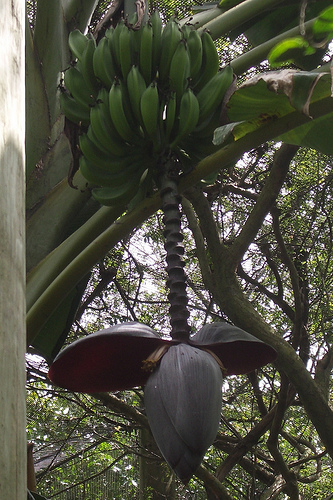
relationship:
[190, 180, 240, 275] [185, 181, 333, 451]
shadow on wood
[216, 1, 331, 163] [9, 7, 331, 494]
leaves on tree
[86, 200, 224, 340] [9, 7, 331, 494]
sky through tree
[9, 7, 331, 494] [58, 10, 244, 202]
tree under bananas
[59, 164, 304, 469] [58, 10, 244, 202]
part hanging bananas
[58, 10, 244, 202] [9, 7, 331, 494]
bananas on tree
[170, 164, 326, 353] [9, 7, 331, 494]
branch on tree